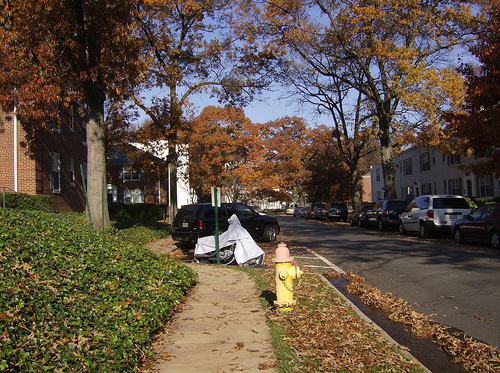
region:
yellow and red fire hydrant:
[268, 237, 306, 313]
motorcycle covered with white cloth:
[188, 212, 267, 270]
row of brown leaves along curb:
[327, 258, 493, 368]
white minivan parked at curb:
[396, 190, 471, 236]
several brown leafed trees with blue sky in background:
[174, 5, 348, 196]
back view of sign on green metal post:
[208, 182, 225, 262]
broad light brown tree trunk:
[80, 103, 113, 229]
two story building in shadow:
[395, 149, 465, 194]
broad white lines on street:
[297, 243, 349, 274]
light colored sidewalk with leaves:
[152, 260, 278, 369]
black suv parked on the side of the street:
[173, 198, 214, 234]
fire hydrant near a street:
[275, 230, 295, 330]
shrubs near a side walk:
[25, 201, 165, 346]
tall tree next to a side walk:
[90, 15, 110, 240]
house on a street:
[130, 136, 165, 211]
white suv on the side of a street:
[410, 185, 465, 221]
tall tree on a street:
[375, 90, 405, 200]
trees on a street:
[210, 105, 320, 192]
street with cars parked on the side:
[340, 215, 405, 266]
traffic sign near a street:
[207, 185, 227, 265]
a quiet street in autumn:
[233, 122, 485, 363]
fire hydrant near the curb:
[265, 237, 351, 319]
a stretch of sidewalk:
[161, 265, 266, 370]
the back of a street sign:
[205, 180, 221, 232]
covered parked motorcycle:
[191, 210, 266, 265]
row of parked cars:
[347, 185, 493, 245]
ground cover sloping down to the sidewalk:
[1, 207, 181, 362]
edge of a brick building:
[0, 111, 75, 202]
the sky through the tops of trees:
[255, 111, 405, 136]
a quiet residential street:
[102, 115, 467, 370]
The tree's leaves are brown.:
[1, 0, 141, 121]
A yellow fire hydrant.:
[265, 230, 305, 310]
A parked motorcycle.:
[190, 215, 265, 276]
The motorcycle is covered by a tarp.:
[185, 215, 266, 265]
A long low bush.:
[0, 195, 182, 370]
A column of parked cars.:
[301, 185, 493, 241]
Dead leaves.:
[285, 300, 375, 370]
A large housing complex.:
[357, 131, 493, 207]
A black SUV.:
[170, 195, 271, 245]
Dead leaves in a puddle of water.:
[373, 263, 498, 370]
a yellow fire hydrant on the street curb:
[271, 240, 302, 312]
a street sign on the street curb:
[209, 184, 224, 264]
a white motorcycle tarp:
[195, 213, 264, 268]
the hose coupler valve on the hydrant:
[288, 265, 301, 281]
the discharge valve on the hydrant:
[277, 268, 287, 278]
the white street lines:
[298, 217, 351, 267]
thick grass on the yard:
[0, 206, 190, 371]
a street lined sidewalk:
[149, 261, 274, 371]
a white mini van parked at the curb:
[398, 193, 470, 238]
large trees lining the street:
[290, 0, 498, 222]